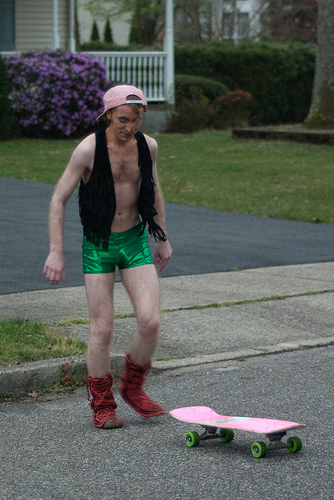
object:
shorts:
[81, 222, 155, 273]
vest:
[77, 129, 166, 252]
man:
[42, 83, 172, 430]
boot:
[87, 373, 123, 428]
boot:
[120, 354, 168, 416]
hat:
[96, 85, 147, 119]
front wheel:
[286, 437, 301, 454]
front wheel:
[250, 440, 268, 460]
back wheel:
[183, 428, 197, 446]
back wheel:
[218, 428, 233, 443]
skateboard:
[168, 405, 304, 457]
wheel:
[250, 439, 267, 459]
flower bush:
[0, 50, 109, 135]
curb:
[0, 358, 127, 394]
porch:
[1, 51, 165, 103]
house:
[0, 0, 176, 133]